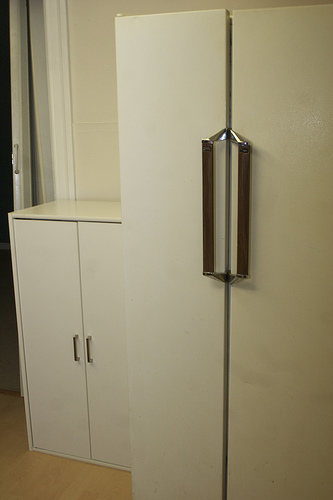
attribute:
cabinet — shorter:
[5, 196, 139, 477]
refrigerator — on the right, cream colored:
[113, 0, 330, 499]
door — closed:
[74, 216, 138, 477]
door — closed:
[10, 211, 96, 464]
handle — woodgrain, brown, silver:
[228, 125, 254, 287]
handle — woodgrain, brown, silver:
[199, 125, 231, 285]